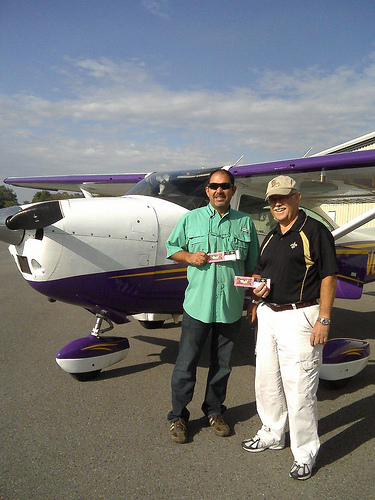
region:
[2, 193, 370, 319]
Airplane fuselage painted purple on the bottom.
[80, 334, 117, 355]
Yellow swoosh marks on the wheel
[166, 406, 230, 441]
man is wearing brown tennis shoes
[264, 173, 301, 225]
older man is wearing a tan baseball cap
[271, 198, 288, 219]
older man has a mustache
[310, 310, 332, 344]
wearing a watch on his left wrist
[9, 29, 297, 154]
scattered clouds in the sky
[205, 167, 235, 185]
man is balding with dark hair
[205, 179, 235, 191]
man is wearing sunglasses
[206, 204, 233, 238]
glasses hanging from his neck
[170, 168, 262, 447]
man in green is standing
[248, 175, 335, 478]
man in black is standing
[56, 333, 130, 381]
the front wheel of a plane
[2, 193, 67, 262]
propeller of a plane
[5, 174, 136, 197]
right wing of a plane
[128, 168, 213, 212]
window on a plane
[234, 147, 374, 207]
wing on a plane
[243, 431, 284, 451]
shoe of a man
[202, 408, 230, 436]
a man's brown shoe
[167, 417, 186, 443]
a man's brown shoe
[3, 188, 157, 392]
plane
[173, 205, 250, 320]
man wearing green shirt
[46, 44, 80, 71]
white clouds in blue sky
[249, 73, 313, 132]
white clouds in blue sky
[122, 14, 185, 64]
white clouds in blue sky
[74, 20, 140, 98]
white clouds in blue sky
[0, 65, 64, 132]
white clouds in blue sky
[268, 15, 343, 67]
white clouds in blue sky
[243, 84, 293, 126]
white clouds in blue sky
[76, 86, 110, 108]
white clouds in blue sky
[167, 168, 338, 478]
two men standing in front of a plane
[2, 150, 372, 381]
a white and purple plane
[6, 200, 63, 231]
a black propeller on a plane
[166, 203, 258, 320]
man wearing a green button-down shirt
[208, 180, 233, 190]
man wearing black sunglasses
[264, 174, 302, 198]
man wearing a cap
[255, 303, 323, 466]
man wearing white pants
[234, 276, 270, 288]
man holding a ticket in his hand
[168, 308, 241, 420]
man wearing dark blue jeans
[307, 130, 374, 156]
white roof of a building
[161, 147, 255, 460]
this is a person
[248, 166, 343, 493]
this is a person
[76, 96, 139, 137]
this is a cloud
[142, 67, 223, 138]
this is a cloud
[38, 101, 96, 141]
this is a cloud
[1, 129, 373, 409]
this is a plane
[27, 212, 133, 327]
this is a plane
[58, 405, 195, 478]
this is a tarmacked road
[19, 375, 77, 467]
this is a tarmacked road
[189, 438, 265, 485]
this is a tarmacked road